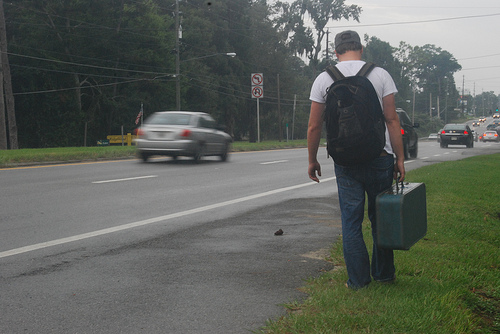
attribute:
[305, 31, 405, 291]
man — walking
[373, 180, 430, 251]
suitcase — green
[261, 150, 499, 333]
grass — here, green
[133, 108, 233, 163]
car — gray, driving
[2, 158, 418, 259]
line — white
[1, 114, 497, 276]
road — here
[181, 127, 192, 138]
light — red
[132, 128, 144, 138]
light — red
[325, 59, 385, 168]
backpack — brown, black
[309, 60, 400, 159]
shirt — short sleeved, white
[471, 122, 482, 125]
headlights — on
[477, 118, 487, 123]
headlights — on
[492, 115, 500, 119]
headlights — on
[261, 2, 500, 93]
sky — grey, overcast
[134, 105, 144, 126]
flag — here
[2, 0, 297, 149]
trees — dark, green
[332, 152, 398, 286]
jeans — blue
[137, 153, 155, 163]
wheel — here